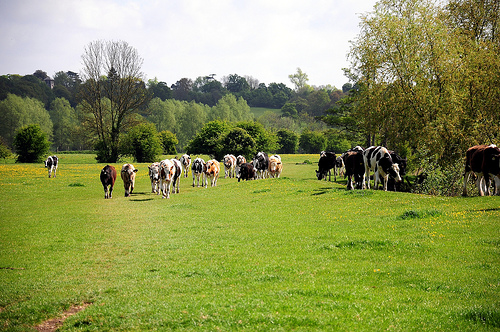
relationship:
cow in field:
[95, 160, 122, 200] [10, 146, 483, 311]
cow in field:
[221, 152, 237, 181] [8, 156, 498, 327]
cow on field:
[42, 154, 66, 181] [8, 156, 498, 327]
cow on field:
[119, 164, 133, 196] [8, 156, 498, 327]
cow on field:
[98, 160, 118, 197] [8, 156, 498, 327]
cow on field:
[313, 147, 336, 184] [8, 156, 498, 327]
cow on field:
[363, 141, 399, 192] [8, 156, 498, 327]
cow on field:
[463, 144, 497, 201] [8, 156, 498, 327]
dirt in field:
[23, 293, 125, 330] [8, 156, 498, 327]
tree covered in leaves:
[341, 0, 498, 198] [374, 17, 484, 145]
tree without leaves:
[77, 25, 164, 165] [82, 37, 152, 122]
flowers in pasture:
[3, 166, 32, 173] [0, 148, 483, 330]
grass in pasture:
[0, 152, 499, 329] [0, 148, 483, 330]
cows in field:
[42, 136, 498, 214] [8, 156, 498, 327]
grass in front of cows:
[0, 152, 499, 329] [42, 143, 499, 200]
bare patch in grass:
[28, 295, 93, 330] [1, 169, 493, 329]